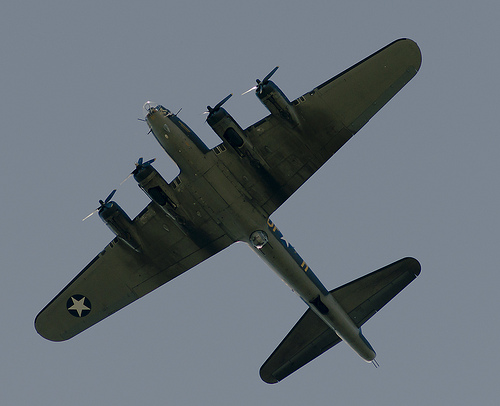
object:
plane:
[31, 35, 424, 387]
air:
[0, 0, 500, 406]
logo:
[64, 293, 92, 318]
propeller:
[241, 64, 282, 97]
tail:
[255, 254, 426, 387]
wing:
[210, 36, 422, 219]